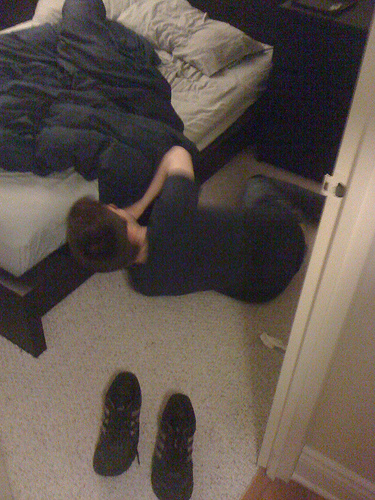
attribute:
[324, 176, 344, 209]
plate — white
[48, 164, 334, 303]
boy — young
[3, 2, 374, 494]
doorway — open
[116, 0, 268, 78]
pillow — light blue, wrinkled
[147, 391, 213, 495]
shoe — dark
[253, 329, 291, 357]
sock — white, grey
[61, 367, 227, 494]
shoes — dark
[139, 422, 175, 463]
stripes — lighter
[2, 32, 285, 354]
bed — platform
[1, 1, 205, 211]
comforter — winter weight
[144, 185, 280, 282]
shirt — dark, short sleeved, tee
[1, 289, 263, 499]
carpet — beige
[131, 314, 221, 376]
flooring — wood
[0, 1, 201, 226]
blanket — dark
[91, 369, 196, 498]
shoes — dark, lighter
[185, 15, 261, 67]
pillowcase — white, wrinkled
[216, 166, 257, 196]
bedroom carpet — light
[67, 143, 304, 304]
man — lying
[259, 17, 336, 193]
night stand — black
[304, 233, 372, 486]
wall — beige, painted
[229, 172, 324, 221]
jeans — blue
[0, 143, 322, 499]
carpet — light colored, berber, thick, white, rough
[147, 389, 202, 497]
shoe — black, adidas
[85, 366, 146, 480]
shoe — black, adidas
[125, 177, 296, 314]
shirt — blue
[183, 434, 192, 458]
stripe — light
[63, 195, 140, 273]
hair — short, brown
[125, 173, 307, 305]
shirt — short sleeve, blue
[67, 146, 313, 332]
boy — laying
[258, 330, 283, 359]
paper — lying